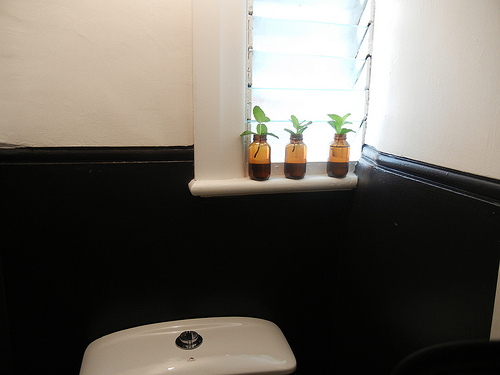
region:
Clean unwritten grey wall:
[16, 13, 184, 105]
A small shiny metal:
[172, 327, 209, 354]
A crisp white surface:
[218, 337, 289, 364]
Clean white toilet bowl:
[83, 315, 299, 371]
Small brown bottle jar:
[245, 133, 274, 182]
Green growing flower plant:
[321, 107, 356, 137]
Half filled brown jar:
[278, 133, 312, 185]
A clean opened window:
[271, 94, 355, 118]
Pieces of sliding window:
[246, 13, 367, 85]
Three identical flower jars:
[237, 99, 363, 186]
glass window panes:
[265, 10, 325, 73]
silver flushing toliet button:
[151, 311, 203, 364]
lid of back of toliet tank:
[93, 320, 278, 372]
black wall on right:
[336, 226, 428, 301]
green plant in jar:
[240, 104, 278, 184]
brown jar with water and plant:
[248, 132, 273, 189]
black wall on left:
[38, 227, 194, 271]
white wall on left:
[71, 35, 165, 118]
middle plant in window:
[285, 116, 317, 180]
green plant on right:
[321, 110, 365, 199]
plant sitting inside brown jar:
[241, 102, 272, 179]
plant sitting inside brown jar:
[281, 115, 313, 178]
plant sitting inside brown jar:
[324, 110, 354, 175]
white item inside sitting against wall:
[75, 317, 303, 374]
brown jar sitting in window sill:
[245, 133, 273, 178]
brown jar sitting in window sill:
[285, 132, 308, 177]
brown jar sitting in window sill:
[326, 134, 356, 176]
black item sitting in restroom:
[398, 342, 498, 370]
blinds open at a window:
[248, 0, 365, 163]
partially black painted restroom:
[0, 0, 495, 374]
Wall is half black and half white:
[10, 17, 476, 352]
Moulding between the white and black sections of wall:
[3, 130, 495, 205]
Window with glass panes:
[185, 5, 370, 198]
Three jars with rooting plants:
[225, 108, 355, 176]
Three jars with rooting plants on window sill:
[165, 100, 356, 185]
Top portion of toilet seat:
[81, 307, 296, 368]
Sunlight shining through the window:
[201, 6, 382, 176]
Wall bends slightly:
[362, 11, 389, 179]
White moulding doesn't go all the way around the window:
[175, 0, 370, 192]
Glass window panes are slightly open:
[236, 3, 366, 167]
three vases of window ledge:
[242, 104, 350, 178]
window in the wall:
[246, 4, 368, 149]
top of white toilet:
[77, 309, 293, 374]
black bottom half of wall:
[7, 144, 487, 373]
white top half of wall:
[4, 1, 499, 173]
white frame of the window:
[194, 5, 253, 174]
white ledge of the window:
[190, 172, 357, 193]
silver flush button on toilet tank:
[175, 328, 202, 350]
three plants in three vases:
[249, 110, 354, 137]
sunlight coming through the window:
[243, 6, 360, 152]